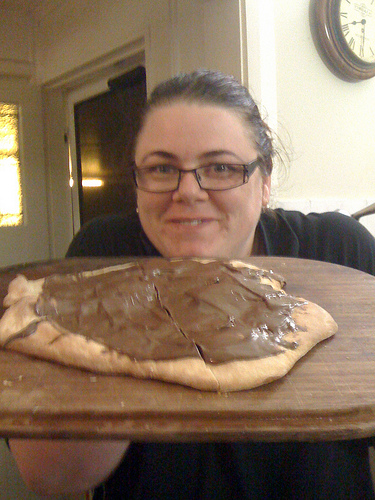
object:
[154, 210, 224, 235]
smile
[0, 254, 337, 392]
crust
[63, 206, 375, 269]
shirt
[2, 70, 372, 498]
woman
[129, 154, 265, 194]
glasses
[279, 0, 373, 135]
wall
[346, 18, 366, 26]
hand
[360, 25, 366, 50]
hand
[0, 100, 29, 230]
window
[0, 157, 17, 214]
light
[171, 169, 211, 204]
nose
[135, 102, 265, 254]
face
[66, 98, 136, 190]
window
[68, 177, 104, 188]
light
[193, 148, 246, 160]
eyebrow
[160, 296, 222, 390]
cut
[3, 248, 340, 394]
bread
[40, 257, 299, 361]
chocolate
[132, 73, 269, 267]
woman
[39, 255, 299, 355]
spread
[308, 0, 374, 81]
clock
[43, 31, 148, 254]
door frame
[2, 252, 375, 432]
plate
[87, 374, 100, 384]
crumb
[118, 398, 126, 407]
crumb